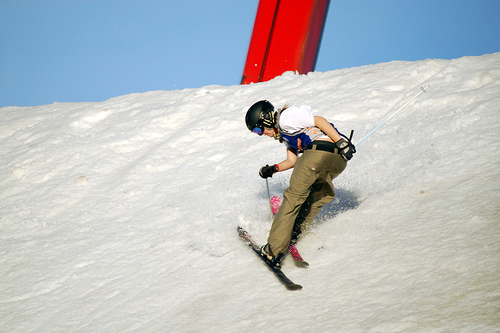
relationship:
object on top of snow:
[242, 0, 329, 84] [3, 53, 496, 332]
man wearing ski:
[245, 100, 357, 269] [238, 223, 302, 292]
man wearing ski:
[245, 100, 357, 269] [272, 195, 308, 270]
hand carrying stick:
[260, 163, 279, 179] [265, 177, 273, 201]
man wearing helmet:
[245, 100, 357, 269] [245, 99, 272, 131]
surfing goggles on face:
[251, 122, 265, 136] [259, 125, 275, 138]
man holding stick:
[245, 100, 357, 269] [265, 177, 273, 201]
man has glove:
[245, 100, 357, 269] [339, 138, 356, 161]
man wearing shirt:
[245, 100, 357, 269] [273, 109, 330, 151]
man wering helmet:
[245, 100, 357, 269] [245, 99, 272, 131]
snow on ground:
[3, 53, 496, 332] [102, 179, 240, 300]